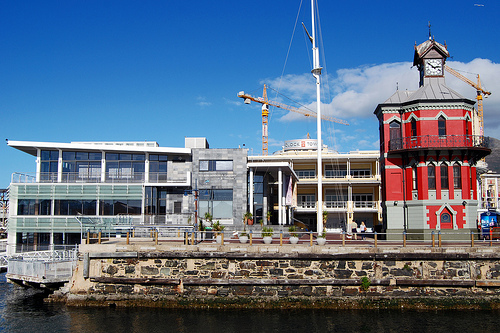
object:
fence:
[85, 227, 499, 246]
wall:
[63, 243, 500, 309]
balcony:
[386, 133, 488, 155]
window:
[425, 161, 435, 192]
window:
[436, 161, 448, 190]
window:
[450, 162, 460, 189]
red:
[386, 173, 401, 198]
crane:
[233, 84, 350, 158]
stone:
[340, 284, 360, 295]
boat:
[5, 247, 83, 289]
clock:
[420, 58, 445, 78]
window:
[435, 112, 447, 139]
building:
[476, 167, 499, 215]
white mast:
[309, 0, 326, 238]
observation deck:
[385, 132, 492, 162]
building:
[4, 136, 209, 288]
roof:
[371, 22, 476, 114]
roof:
[246, 133, 389, 161]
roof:
[6, 136, 210, 156]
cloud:
[258, 56, 499, 124]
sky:
[0, 2, 498, 186]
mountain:
[475, 135, 498, 171]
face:
[422, 58, 442, 76]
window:
[406, 114, 417, 141]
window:
[461, 109, 474, 141]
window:
[385, 118, 403, 151]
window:
[438, 206, 453, 230]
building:
[270, 131, 390, 243]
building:
[189, 148, 246, 237]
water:
[0, 269, 499, 332]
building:
[372, 20, 493, 242]